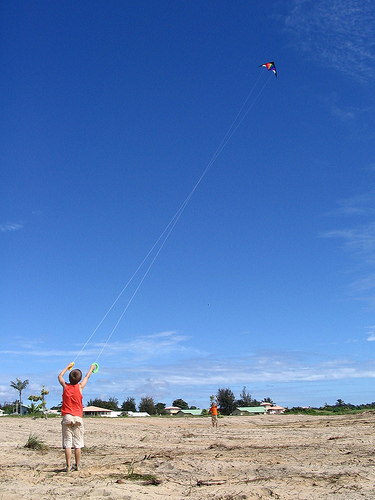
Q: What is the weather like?
A: It is cloudy.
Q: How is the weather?
A: It is cloudy.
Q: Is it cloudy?
A: Yes, it is cloudy.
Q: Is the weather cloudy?
A: Yes, it is cloudy.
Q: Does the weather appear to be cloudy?
A: Yes, it is cloudy.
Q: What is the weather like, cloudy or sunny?
A: It is cloudy.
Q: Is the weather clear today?
A: No, it is cloudy.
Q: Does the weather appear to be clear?
A: No, it is cloudy.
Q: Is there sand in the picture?
A: Yes, there is sand.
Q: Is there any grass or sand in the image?
A: Yes, there is sand.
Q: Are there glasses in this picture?
A: No, there are no glasses.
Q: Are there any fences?
A: No, there are no fences.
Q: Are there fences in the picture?
A: No, there are no fences.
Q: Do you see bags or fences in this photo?
A: No, there are no fences or bags.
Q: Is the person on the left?
A: Yes, the person is on the left of the image.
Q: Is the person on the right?
A: No, the person is on the left of the image.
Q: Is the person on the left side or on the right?
A: The person is on the left of the image.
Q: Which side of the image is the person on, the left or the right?
A: The person is on the left of the image.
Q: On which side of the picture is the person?
A: The person is on the left of the image.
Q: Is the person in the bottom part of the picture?
A: Yes, the person is in the bottom of the image.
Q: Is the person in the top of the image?
A: No, the person is in the bottom of the image.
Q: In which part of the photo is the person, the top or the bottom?
A: The person is in the bottom of the image.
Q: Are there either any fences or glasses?
A: No, there are no fences or glasses.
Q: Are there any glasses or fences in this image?
A: No, there are no fences or glasses.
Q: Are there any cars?
A: No, there are no cars.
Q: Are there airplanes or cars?
A: No, there are no cars or airplanes.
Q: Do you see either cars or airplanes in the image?
A: No, there are no cars or airplanes.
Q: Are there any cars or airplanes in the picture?
A: No, there are no cars or airplanes.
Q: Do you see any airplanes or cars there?
A: No, there are no cars or airplanes.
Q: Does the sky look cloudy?
A: Yes, the sky is cloudy.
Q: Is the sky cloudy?
A: Yes, the sky is cloudy.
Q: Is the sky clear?
A: No, the sky is cloudy.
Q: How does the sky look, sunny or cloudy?
A: The sky is cloudy.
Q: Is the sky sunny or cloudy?
A: The sky is cloudy.